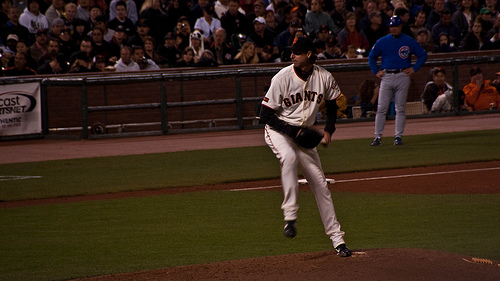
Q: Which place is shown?
A: It is a field.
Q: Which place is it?
A: It is a field.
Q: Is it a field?
A: Yes, it is a field.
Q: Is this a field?
A: Yes, it is a field.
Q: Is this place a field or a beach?
A: It is a field.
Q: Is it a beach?
A: No, it is a field.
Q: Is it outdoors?
A: Yes, it is outdoors.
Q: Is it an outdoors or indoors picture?
A: It is outdoors.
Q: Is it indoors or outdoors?
A: It is outdoors.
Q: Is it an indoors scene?
A: No, it is outdoors.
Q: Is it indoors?
A: No, it is outdoors.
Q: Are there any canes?
A: No, there are no canes.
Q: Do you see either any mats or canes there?
A: No, there are no canes or mats.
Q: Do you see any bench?
A: No, there are no benches.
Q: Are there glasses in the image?
A: No, there are no glasses.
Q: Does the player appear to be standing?
A: Yes, the player is standing.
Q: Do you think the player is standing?
A: Yes, the player is standing.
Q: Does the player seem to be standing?
A: Yes, the player is standing.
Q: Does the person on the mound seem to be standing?
A: Yes, the player is standing.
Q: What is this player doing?
A: The player is standing.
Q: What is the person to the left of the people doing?
A: The player is standing.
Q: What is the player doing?
A: The player is standing.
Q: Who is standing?
A: The player is standing.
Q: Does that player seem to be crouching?
A: No, the player is standing.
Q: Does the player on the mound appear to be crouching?
A: No, the player is standing.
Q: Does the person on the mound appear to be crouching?
A: No, the player is standing.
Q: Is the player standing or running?
A: The player is standing.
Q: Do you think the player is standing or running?
A: The player is standing.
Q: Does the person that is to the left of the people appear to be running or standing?
A: The player is standing.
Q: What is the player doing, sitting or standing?
A: The player is standing.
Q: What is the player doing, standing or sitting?
A: The player is standing.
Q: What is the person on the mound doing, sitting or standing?
A: The player is standing.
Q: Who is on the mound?
A: The player is on the mound.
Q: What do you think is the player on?
A: The player is on the mound.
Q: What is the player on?
A: The player is on the mound.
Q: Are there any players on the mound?
A: Yes, there is a player on the mound.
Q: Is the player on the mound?
A: Yes, the player is on the mound.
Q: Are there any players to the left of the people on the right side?
A: Yes, there is a player to the left of the people.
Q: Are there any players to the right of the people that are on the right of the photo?
A: No, the player is to the left of the people.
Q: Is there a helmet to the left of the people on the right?
A: No, there is a player to the left of the people.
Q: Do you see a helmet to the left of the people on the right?
A: No, there is a player to the left of the people.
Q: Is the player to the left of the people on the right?
A: Yes, the player is to the left of the people.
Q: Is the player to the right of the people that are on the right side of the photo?
A: No, the player is to the left of the people.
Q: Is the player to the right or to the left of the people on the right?
A: The player is to the left of the people.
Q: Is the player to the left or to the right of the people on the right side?
A: The player is to the left of the people.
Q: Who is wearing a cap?
A: The player is wearing a cap.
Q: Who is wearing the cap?
A: The player is wearing a cap.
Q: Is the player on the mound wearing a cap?
A: Yes, the player is wearing a cap.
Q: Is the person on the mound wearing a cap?
A: Yes, the player is wearing a cap.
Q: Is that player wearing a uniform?
A: No, the player is wearing a cap.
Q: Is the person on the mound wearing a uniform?
A: No, the player is wearing a cap.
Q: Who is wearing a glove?
A: The player is wearing a glove.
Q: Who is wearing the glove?
A: The player is wearing a glove.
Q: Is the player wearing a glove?
A: Yes, the player is wearing a glove.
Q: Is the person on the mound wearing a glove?
A: Yes, the player is wearing a glove.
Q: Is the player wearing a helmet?
A: No, the player is wearing a glove.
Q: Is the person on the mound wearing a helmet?
A: No, the player is wearing a glove.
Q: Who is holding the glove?
A: The player is holding the glove.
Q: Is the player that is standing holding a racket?
A: No, the player is holding the glove.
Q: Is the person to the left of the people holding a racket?
A: No, the player is holding the glove.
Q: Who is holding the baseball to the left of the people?
A: The player is holding the baseball.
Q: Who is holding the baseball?
A: The player is holding the baseball.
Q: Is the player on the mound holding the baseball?
A: Yes, the player is holding the baseball.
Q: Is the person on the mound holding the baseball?
A: Yes, the player is holding the baseball.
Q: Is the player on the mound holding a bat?
A: No, the player is holding the baseball.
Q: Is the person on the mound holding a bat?
A: No, the player is holding the baseball.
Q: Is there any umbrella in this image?
A: No, there are no umbrellas.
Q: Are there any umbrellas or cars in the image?
A: No, there are no umbrellas or cars.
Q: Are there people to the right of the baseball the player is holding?
A: Yes, there are people to the right of the baseball.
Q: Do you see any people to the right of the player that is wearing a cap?
A: Yes, there are people to the right of the player.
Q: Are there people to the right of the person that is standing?
A: Yes, there are people to the right of the player.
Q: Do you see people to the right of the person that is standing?
A: Yes, there are people to the right of the player.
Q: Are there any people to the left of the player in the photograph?
A: No, the people are to the right of the player.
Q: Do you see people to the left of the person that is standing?
A: No, the people are to the right of the player.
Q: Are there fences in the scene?
A: Yes, there is a fence.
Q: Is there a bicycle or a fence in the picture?
A: Yes, there is a fence.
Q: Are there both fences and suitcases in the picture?
A: No, there is a fence but no suitcases.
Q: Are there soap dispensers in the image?
A: No, there are no soap dispensers.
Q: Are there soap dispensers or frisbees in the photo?
A: No, there are no soap dispensers or frisbees.